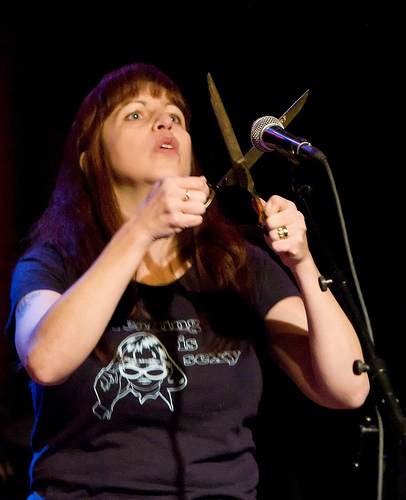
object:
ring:
[277, 227, 283, 239]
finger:
[269, 223, 305, 240]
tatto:
[17, 290, 38, 318]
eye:
[124, 110, 143, 121]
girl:
[93, 330, 187, 420]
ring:
[184, 189, 190, 200]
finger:
[177, 188, 207, 203]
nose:
[153, 111, 174, 131]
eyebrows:
[114, 101, 146, 121]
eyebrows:
[165, 102, 175, 107]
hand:
[257, 194, 306, 266]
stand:
[318, 157, 406, 499]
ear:
[79, 150, 87, 172]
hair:
[26, 62, 247, 360]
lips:
[154, 134, 179, 156]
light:
[151, 235, 181, 273]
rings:
[278, 225, 288, 238]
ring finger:
[269, 227, 304, 241]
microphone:
[251, 116, 325, 169]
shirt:
[6, 215, 302, 500]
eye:
[169, 113, 183, 126]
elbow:
[334, 368, 371, 408]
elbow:
[22, 340, 72, 385]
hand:
[144, 175, 210, 237]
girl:
[5, 65, 368, 500]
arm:
[15, 216, 148, 384]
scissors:
[204, 72, 308, 237]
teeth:
[161, 143, 173, 148]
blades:
[206, 72, 242, 163]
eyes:
[124, 110, 183, 125]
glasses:
[116, 364, 167, 379]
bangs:
[97, 62, 187, 119]